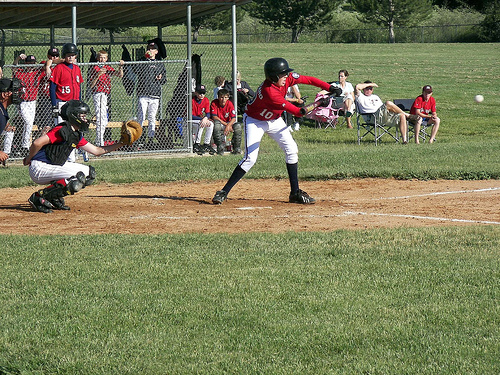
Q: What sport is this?
A: Baseball.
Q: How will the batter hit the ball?
A: With his bat.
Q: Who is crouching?
A: The catcher.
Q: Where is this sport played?
A: On a baseball field.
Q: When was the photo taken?
A: Daytime.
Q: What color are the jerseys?
A: Red.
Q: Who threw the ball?
A: The pitcher.